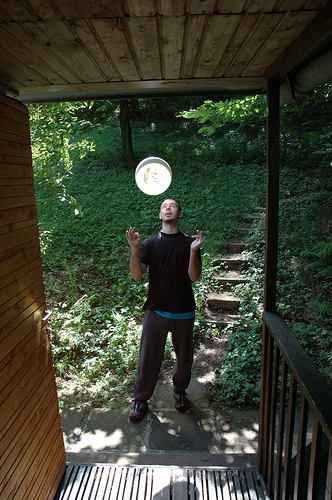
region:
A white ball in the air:
[132, 153, 173, 194]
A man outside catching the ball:
[126, 196, 206, 418]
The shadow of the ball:
[144, 476, 199, 499]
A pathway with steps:
[190, 178, 307, 373]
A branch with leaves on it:
[170, 96, 265, 136]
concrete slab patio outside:
[60, 403, 318, 487]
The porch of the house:
[67, 460, 267, 499]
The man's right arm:
[121, 225, 144, 281]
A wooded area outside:
[100, 100, 270, 162]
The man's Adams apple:
[166, 223, 171, 229]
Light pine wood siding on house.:
[6, 88, 60, 496]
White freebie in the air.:
[129, 153, 174, 196]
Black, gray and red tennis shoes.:
[124, 390, 194, 424]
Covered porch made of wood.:
[14, 86, 292, 495]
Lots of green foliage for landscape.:
[37, 109, 324, 413]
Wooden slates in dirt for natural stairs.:
[164, 189, 325, 382]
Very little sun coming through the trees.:
[18, 96, 288, 226]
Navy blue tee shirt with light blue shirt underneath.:
[121, 196, 207, 426]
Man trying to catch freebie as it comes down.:
[122, 154, 206, 424]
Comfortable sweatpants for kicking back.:
[126, 197, 208, 425]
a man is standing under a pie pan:
[117, 154, 207, 285]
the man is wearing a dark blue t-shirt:
[134, 229, 202, 313]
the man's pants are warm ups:
[130, 314, 195, 399]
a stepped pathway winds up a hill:
[203, 177, 324, 380]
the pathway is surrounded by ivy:
[163, 163, 331, 389]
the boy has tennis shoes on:
[123, 395, 206, 423]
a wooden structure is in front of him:
[4, 314, 265, 498]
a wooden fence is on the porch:
[256, 309, 329, 499]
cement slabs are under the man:
[73, 405, 224, 453]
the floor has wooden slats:
[64, 462, 266, 499]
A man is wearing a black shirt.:
[122, 200, 200, 422]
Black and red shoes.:
[125, 387, 200, 423]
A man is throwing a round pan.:
[123, 154, 206, 420]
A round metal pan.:
[135, 155, 171, 194]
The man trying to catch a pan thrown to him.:
[123, 155, 225, 425]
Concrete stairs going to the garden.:
[202, 196, 266, 329]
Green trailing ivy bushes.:
[282, 105, 328, 315]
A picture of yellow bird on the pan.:
[133, 155, 170, 193]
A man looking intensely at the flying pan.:
[126, 154, 204, 426]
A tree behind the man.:
[109, 99, 136, 160]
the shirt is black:
[133, 217, 200, 319]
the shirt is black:
[122, 221, 242, 304]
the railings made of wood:
[248, 300, 318, 481]